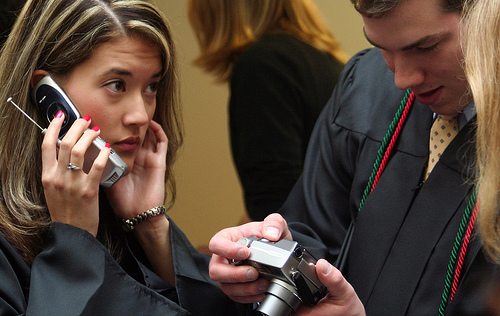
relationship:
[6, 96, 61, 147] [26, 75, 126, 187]
antenna on cell phone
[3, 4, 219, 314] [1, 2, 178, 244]
woman has hair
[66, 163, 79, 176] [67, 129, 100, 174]
ring on finger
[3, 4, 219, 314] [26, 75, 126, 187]
woman holding cell phone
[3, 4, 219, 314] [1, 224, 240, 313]
woman wearing jacket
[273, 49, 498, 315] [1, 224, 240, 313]
man wearing jacket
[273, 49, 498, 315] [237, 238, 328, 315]
man holding camera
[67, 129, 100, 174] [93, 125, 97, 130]
finger has red polish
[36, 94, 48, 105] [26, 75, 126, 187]
logo on cell phone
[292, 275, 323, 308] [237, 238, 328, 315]
strap on camera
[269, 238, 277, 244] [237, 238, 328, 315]
light on top of camera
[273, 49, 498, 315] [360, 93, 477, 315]
man wearing cord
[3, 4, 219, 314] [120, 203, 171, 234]
woman wearing bracelet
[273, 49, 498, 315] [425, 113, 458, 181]
man wearing tie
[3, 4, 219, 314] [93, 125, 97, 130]
woman wearing red polish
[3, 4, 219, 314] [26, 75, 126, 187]
woman on cell phone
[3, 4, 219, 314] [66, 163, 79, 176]
woman wearing ring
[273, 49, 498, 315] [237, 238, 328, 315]
man looking at camera